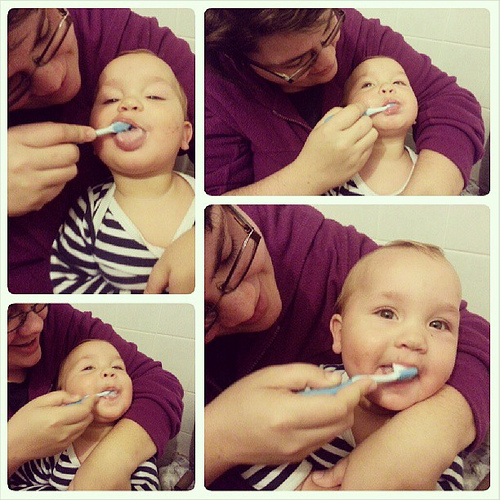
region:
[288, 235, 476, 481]
Baby getting his teeth brushed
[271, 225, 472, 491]
Baby having his teeth cleaned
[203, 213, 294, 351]
Person wearing dark frame eyeglasses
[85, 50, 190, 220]
Child opening his mouth for a toothbrush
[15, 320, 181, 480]
Person holding child while brushing his teeth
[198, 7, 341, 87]
Person with dark colored hair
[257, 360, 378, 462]
Hand holding a toothbrush handle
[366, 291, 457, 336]
Eyes of a small child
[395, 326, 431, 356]
Nose of a small child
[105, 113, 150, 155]
Mouth of a small child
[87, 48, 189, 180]
the face of a baby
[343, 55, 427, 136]
the face of a baby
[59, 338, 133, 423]
the face of a baby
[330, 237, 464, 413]
the face of a baby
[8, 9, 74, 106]
a pair of glasses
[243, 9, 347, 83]
a pair of glasses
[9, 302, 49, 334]
a pair of glasses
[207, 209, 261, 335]
a pair of glasses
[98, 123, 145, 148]
part of a toothbrush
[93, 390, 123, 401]
part of a toothbrush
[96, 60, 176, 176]
cute face of the boy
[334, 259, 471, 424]
innocent face of the boy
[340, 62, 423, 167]
lovely face of boy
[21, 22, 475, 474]
cute boy with lovely pics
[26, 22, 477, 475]
boy and mom in picture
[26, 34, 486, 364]
four different pics of a boy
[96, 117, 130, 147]
a small spoon of boy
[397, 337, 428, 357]
nose of the boy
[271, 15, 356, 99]
spectacles of the women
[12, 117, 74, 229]
hand of the women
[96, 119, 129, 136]
a white and blue tooth brush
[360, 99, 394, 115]
a white and blue tooth brush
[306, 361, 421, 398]
a white and blue tooth brush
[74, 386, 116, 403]
a white and blue tooth brush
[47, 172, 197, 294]
a black and white striped shirt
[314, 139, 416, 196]
a black and white striped shirt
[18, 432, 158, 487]
a black and white striped shirt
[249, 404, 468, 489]
a black and white striped shirt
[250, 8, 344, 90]
a pair of eyeglasses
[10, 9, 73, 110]
a pair of eyeglasses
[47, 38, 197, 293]
A kid in the picture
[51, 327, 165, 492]
A kid in the picture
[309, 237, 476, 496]
A kid in the picture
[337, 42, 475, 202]
A kid in the picture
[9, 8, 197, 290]
A woman helping a kid brush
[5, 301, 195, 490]
A woman helping a kid brush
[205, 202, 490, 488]
A woman helping a kid brush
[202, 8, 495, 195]
A woman helping a kid brush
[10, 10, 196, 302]
A kid brushing in the picture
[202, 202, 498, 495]
A kid brushing in the picture